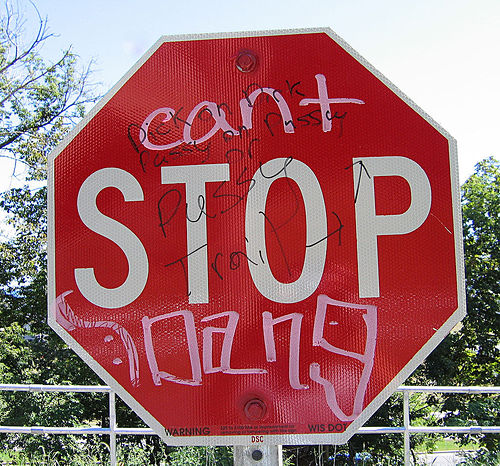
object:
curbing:
[411, 447, 478, 452]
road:
[338, 449, 480, 464]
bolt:
[244, 399, 267, 420]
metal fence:
[3, 381, 120, 464]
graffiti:
[41, 64, 471, 451]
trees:
[464, 161, 500, 462]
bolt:
[236, 51, 255, 72]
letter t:
[158, 163, 230, 304]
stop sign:
[33, 23, 474, 465]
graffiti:
[117, 289, 382, 429]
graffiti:
[138, 72, 365, 150]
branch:
[0, 72, 40, 122]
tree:
[0, 0, 99, 157]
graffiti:
[257, 103, 345, 141]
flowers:
[330, 445, 374, 463]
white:
[298, 434, 349, 446]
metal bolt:
[234, 50, 257, 74]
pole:
[230, 445, 282, 465]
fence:
[1, 380, 500, 466]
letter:
[53, 162, 233, 308]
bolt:
[251, 450, 262, 462]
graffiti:
[160, 156, 326, 304]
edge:
[145, 423, 366, 448]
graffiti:
[343, 160, 375, 201]